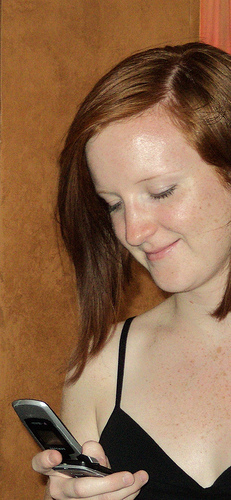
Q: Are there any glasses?
A: No, there are no glasses.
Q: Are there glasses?
A: No, there are no glasses.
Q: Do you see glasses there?
A: No, there are no glasses.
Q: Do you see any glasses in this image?
A: No, there are no glasses.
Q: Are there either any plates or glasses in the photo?
A: No, there are no glasses or plates.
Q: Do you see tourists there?
A: No, there are no tourists.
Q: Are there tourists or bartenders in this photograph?
A: No, there are no tourists or bartenders.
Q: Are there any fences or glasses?
A: No, there are no glasses or fences.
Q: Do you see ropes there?
A: No, there are no ropes.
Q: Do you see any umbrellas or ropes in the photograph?
A: No, there are no ropes or umbrellas.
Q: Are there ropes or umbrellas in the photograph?
A: No, there are no ropes or umbrellas.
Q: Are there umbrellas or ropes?
A: No, there are no ropes or umbrellas.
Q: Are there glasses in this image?
A: No, there are no glasses.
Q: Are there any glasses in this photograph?
A: No, there are no glasses.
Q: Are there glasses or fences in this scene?
A: No, there are no glasses or fences.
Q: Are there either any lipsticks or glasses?
A: No, there are no glasses or lipsticks.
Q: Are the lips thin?
A: Yes, the lips are thin.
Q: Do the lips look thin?
A: Yes, the lips are thin.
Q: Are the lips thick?
A: No, the lips are thin.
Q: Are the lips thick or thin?
A: The lips are thin.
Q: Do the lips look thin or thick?
A: The lips are thin.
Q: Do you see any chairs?
A: No, there are no chairs.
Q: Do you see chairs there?
A: No, there are no chairs.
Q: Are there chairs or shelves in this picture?
A: No, there are no chairs or shelves.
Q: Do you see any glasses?
A: No, there are no glasses.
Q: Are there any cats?
A: No, there are no cats.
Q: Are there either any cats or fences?
A: No, there are no cats or fences.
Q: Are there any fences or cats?
A: No, there are no cats or fences.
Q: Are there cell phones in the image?
A: Yes, there is a cell phone.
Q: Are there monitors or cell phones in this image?
A: Yes, there is a cell phone.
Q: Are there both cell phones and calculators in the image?
A: No, there is a cell phone but no calculators.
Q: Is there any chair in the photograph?
A: No, there are no chairs.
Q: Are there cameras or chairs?
A: No, there are no chairs or cameras.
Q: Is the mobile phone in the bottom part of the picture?
A: Yes, the mobile phone is in the bottom of the image.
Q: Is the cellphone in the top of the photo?
A: No, the cellphone is in the bottom of the image.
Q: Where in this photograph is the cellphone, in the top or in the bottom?
A: The cellphone is in the bottom of the image.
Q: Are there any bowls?
A: No, there are no bowls.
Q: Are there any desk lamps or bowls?
A: No, there are no bowls or desk lamps.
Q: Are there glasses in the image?
A: No, there are no glasses.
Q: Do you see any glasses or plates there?
A: No, there are no glasses or plates.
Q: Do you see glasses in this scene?
A: No, there are no glasses.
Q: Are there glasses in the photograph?
A: No, there are no glasses.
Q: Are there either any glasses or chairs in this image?
A: No, there are no glasses or chairs.